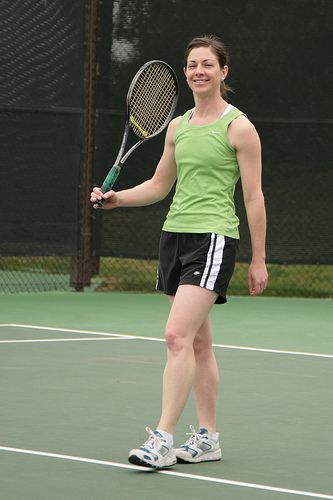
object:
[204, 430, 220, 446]
socks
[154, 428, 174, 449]
socks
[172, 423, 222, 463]
shoe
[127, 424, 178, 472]
shoe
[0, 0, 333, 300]
fence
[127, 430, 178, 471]
foot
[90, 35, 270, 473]
woman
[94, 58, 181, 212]
racket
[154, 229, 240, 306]
shorts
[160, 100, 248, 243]
tank top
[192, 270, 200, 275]
logo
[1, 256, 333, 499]
ground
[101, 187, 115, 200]
fingers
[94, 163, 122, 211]
handle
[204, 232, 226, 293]
line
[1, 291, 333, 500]
tennis court